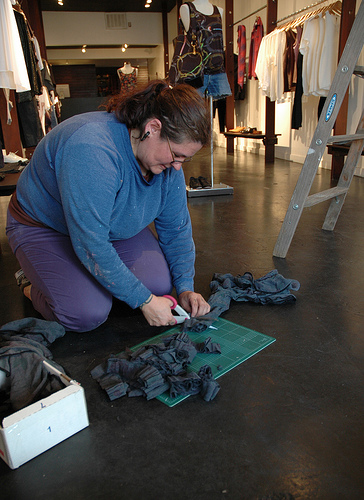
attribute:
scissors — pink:
[158, 290, 220, 334]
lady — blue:
[3, 74, 218, 334]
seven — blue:
[39, 401, 45, 407]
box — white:
[2, 342, 97, 473]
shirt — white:
[317, 4, 344, 93]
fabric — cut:
[110, 346, 274, 446]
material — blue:
[88, 266, 302, 403]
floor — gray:
[212, 162, 283, 265]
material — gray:
[88, 332, 223, 404]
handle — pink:
[161, 292, 178, 311]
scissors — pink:
[161, 291, 218, 330]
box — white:
[0, 359, 91, 470]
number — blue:
[43, 423, 52, 432]